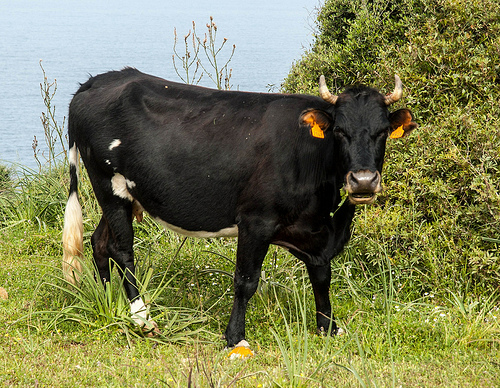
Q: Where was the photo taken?
A: It was taken at the field.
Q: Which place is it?
A: It is a field.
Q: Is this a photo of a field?
A: Yes, it is showing a field.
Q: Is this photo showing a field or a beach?
A: It is showing a field.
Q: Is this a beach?
A: No, it is a field.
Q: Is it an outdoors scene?
A: Yes, it is outdoors.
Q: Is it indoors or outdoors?
A: It is outdoors.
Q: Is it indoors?
A: No, it is outdoors.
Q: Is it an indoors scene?
A: No, it is outdoors.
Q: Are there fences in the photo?
A: No, there are no fences.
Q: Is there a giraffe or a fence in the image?
A: No, there are no fences or giraffes.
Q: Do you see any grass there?
A: Yes, there is grass.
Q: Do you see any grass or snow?
A: Yes, there is grass.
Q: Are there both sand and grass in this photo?
A: No, there is grass but no sand.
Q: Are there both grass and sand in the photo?
A: No, there is grass but no sand.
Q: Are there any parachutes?
A: No, there are no parachutes.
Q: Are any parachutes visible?
A: No, there are no parachutes.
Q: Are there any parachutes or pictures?
A: No, there are no parachutes or pictures.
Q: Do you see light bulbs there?
A: No, there are no light bulbs.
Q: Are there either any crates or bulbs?
A: No, there are no bulbs or crates.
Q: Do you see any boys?
A: No, there are no boys.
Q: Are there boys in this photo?
A: No, there are no boys.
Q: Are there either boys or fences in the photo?
A: No, there are no boys or fences.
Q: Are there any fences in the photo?
A: No, there are no fences.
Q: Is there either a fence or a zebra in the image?
A: No, there are no fences or zebras.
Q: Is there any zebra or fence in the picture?
A: No, there are no fences or zebras.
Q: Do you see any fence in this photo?
A: No, there are no fences.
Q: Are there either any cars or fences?
A: No, there are no fences or cars.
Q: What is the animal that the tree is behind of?
A: The animal is a bull.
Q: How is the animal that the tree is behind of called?
A: The animal is a bull.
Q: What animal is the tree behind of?
A: The tree is behind the bull.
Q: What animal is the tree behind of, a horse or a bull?
A: The tree is behind a bull.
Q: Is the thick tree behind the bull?
A: Yes, the tree is behind the bull.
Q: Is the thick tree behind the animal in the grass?
A: Yes, the tree is behind the bull.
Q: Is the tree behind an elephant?
A: No, the tree is behind the bull.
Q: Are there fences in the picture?
A: No, there are no fences.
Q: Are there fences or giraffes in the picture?
A: No, there are no fences or giraffes.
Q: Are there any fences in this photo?
A: No, there are no fences.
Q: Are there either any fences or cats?
A: No, there are no fences or cats.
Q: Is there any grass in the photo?
A: Yes, there is grass.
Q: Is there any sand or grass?
A: Yes, there is grass.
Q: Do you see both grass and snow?
A: No, there is grass but no snow.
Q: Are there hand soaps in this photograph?
A: No, there are no hand soaps.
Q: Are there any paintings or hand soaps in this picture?
A: No, there are no hand soaps or paintings.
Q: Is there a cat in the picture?
A: No, there are no cats.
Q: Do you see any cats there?
A: No, there are no cats.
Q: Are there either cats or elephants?
A: No, there are no cats or elephants.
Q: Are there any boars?
A: No, there are no boars.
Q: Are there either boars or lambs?
A: No, there are no boars or lambs.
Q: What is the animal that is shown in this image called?
A: The animal is a bull.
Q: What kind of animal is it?
A: The animal is a bull.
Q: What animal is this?
A: This is a bull.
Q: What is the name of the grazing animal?
A: The animal is a bull.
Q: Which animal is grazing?
A: The animal is a bull.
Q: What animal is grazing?
A: The animal is a bull.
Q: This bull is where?
A: The bull is in the grass.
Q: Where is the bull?
A: The bull is in the grass.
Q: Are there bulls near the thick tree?
A: Yes, there is a bull near the tree.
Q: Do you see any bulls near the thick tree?
A: Yes, there is a bull near the tree.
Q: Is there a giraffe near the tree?
A: No, there is a bull near the tree.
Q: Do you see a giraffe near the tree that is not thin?
A: No, there is a bull near the tree.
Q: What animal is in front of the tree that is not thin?
A: The bull is in front of the tree.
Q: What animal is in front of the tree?
A: The bull is in front of the tree.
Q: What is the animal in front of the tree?
A: The animal is a bull.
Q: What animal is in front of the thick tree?
A: The animal is a bull.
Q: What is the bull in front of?
A: The bull is in front of the tree.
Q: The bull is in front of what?
A: The bull is in front of the tree.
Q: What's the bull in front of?
A: The bull is in front of the tree.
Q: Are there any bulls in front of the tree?
A: Yes, there is a bull in front of the tree.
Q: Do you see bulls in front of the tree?
A: Yes, there is a bull in front of the tree.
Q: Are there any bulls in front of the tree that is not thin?
A: Yes, there is a bull in front of the tree.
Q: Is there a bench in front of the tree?
A: No, there is a bull in front of the tree.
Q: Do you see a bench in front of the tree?
A: No, there is a bull in front of the tree.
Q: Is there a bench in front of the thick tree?
A: No, there is a bull in front of the tree.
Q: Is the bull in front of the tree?
A: Yes, the bull is in front of the tree.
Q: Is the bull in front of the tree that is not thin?
A: Yes, the bull is in front of the tree.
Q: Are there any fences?
A: No, there are no fences.